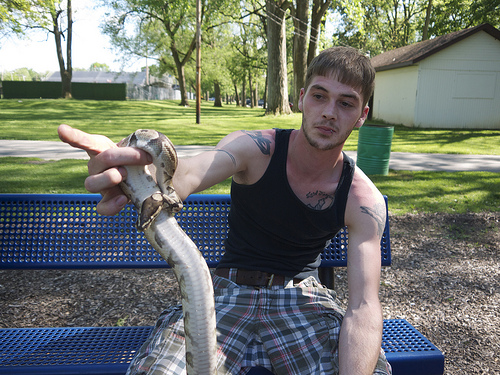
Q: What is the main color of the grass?
A: Green.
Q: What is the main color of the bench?
A: Blue.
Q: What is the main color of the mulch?
A: Brown.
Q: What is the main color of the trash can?
A: Green.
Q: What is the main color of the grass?
A: Green.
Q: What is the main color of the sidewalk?
A: Gray.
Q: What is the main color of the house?
A: White.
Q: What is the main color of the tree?
A: Green.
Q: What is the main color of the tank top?
A: Black.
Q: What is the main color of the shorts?
A: Blue.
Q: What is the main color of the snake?
A: Green.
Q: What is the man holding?
A: A snake.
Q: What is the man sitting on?
A: A blue bench.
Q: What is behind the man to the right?
A: A small shed.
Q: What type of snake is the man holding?
A: A python.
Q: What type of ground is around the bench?
A: Brown mulch.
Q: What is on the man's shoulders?
A: Tattoos.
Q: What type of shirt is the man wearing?
A: A tank top.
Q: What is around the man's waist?
A: A belt.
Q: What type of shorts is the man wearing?
A: Plaid shorts.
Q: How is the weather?
A: Sunny.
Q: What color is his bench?
A: Blue.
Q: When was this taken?
A: Daytime.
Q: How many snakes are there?
A: 1.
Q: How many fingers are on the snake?
A: 2.